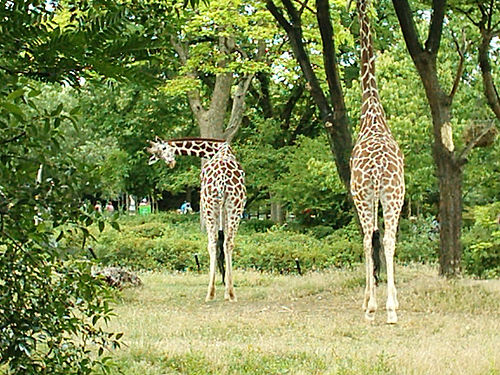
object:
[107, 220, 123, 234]
leaves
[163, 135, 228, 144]
mane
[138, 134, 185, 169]
head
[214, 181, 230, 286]
tail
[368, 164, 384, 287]
tail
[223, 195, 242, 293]
legs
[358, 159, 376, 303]
legs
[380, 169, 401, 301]
legs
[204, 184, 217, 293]
legs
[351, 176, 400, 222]
back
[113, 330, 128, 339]
leaves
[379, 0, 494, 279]
tree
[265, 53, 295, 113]
sky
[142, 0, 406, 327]
two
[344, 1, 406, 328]
one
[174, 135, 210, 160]
bent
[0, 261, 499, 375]
field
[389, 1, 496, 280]
trees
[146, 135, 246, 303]
one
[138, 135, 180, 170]
backwards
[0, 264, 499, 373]
grass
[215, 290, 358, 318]
brown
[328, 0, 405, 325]
giraffes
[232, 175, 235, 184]
brown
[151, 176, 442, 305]
no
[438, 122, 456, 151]
light patch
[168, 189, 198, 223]
someone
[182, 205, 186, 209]
shirt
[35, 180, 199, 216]
athletic field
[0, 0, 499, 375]
background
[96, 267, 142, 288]
one rock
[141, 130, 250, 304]
giraffe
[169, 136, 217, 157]
neck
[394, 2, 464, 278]
trunk